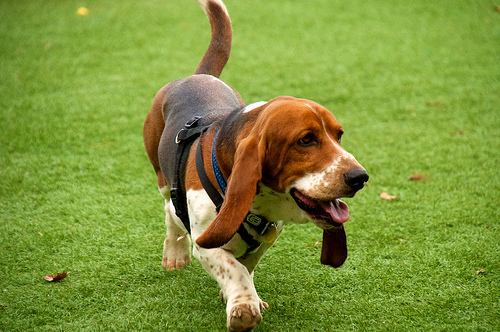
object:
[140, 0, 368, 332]
dog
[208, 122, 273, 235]
collar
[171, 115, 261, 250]
harness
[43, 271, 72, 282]
leaf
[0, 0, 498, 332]
grass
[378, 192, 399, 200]
leaf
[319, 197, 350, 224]
tongue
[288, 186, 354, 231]
mouth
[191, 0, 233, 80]
tail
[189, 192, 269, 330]
front leg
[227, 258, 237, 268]
speckles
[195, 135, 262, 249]
ear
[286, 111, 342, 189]
face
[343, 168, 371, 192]
nose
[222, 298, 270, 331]
front paw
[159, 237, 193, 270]
back paw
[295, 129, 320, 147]
right eye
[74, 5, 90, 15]
ball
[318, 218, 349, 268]
ear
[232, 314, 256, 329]
pads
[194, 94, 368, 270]
head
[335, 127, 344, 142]
left eye